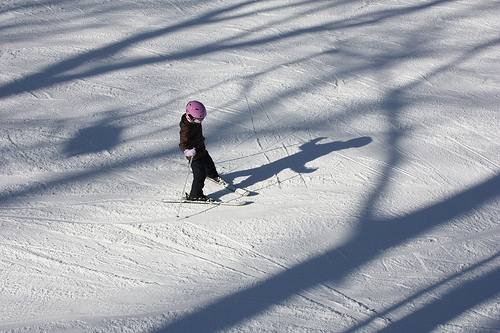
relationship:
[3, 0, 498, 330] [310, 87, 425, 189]
tree shadows on snow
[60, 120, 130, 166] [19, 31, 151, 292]
shadow on slope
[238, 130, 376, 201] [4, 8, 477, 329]
shadow on slope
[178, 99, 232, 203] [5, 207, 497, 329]
person in snow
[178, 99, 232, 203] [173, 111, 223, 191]
person wearing clothes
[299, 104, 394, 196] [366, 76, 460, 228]
shadow on snow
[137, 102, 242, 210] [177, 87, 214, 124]
person wearing helmet